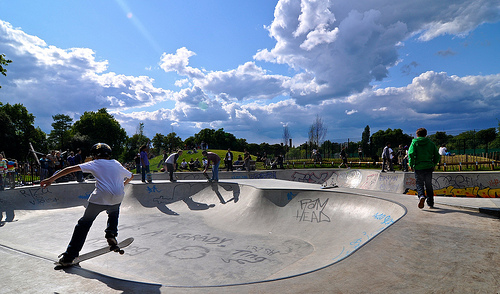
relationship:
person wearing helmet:
[44, 130, 148, 276] [90, 140, 114, 155]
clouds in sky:
[0, 0, 498, 142] [1, 1, 498, 148]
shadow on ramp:
[183, 195, 218, 212] [2, 172, 406, 292]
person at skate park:
[407, 126, 442, 208] [0, 129, 500, 294]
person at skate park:
[44, 130, 148, 276] [0, 129, 500, 294]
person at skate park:
[198, 149, 222, 181] [0, 129, 500, 294]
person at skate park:
[162, 147, 182, 182] [0, 129, 500, 294]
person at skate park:
[138, 144, 149, 183] [0, 129, 500, 294]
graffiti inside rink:
[90, 214, 283, 266] [1, 182, 406, 287]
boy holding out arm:
[46, 141, 145, 269] [38, 160, 90, 184]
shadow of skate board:
[73, 257, 164, 292] [49, 236, 141, 270]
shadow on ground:
[73, 257, 164, 292] [0, 178, 498, 292]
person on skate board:
[44, 123, 149, 281] [59, 221, 151, 281]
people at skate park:
[9, 114, 447, 270] [0, 129, 500, 291]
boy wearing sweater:
[406, 125, 441, 210] [407, 134, 443, 174]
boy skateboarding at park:
[406, 125, 441, 210] [1, 161, 498, 291]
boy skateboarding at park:
[46, 141, 145, 269] [1, 161, 498, 291]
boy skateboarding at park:
[157, 142, 191, 182] [1, 161, 498, 291]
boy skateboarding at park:
[132, 134, 157, 191] [1, 161, 498, 291]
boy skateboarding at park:
[197, 145, 221, 185] [1, 161, 498, 291]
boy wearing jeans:
[46, 141, 145, 269] [61, 203, 122, 247]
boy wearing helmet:
[406, 125, 441, 210] [87, 140, 117, 157]